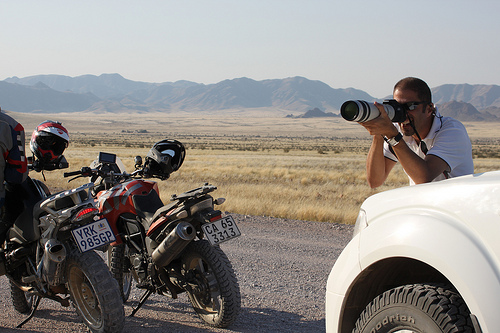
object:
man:
[357, 76, 474, 189]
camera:
[340, 99, 410, 123]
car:
[324, 170, 500, 333]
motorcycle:
[61, 152, 241, 329]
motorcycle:
[0, 149, 125, 332]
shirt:
[379, 106, 474, 186]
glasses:
[393, 101, 433, 112]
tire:
[177, 238, 241, 328]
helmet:
[29, 119, 70, 164]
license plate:
[201, 215, 241, 247]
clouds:
[1, 1, 500, 73]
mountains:
[0, 73, 500, 125]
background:
[1, 1, 498, 150]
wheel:
[345, 282, 475, 333]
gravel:
[0, 211, 360, 333]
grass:
[3, 111, 500, 225]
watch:
[387, 131, 403, 146]